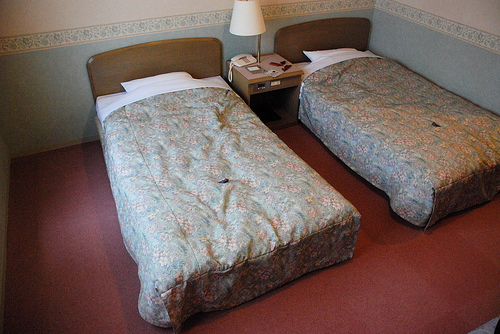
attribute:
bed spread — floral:
[108, 97, 292, 289]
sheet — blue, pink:
[297, 60, 497, 227]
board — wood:
[276, 22, 371, 49]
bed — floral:
[91, 34, 361, 331]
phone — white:
[225, 48, 258, 68]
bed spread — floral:
[82, 68, 370, 332]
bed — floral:
[60, 53, 350, 286]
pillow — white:
[113, 61, 203, 101]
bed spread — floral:
[103, 96, 369, 321]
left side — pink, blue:
[84, 42, 463, 293]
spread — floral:
[251, 233, 308, 268]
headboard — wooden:
[73, 28, 233, 118]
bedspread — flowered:
[94, 79, 367, 326]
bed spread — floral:
[103, 90, 337, 271]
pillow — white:
[118, 70, 202, 102]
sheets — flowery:
[95, 101, 375, 298]